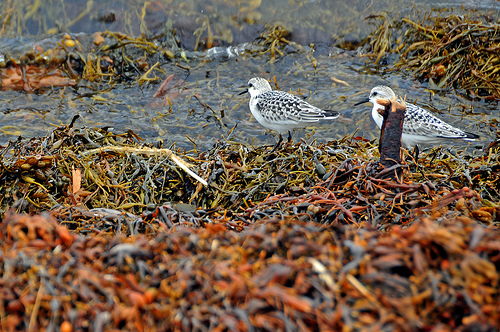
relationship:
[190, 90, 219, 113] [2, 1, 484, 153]
reed growing in water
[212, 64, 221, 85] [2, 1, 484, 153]
reed growing in water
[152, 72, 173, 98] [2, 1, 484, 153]
reed growing in water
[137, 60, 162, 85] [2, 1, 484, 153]
reed growing in water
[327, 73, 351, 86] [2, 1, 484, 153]
reed growing in water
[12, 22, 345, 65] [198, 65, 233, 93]
snake sliring in water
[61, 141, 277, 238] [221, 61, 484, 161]
seaweed near birds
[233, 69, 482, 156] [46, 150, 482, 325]
birds on ground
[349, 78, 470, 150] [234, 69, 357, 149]
bird next to bird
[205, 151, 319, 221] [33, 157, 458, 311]
stuff on ground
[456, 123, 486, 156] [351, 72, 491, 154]
feather on bird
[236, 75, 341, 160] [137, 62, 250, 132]
birds standing near water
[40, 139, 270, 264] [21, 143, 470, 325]
twigs on ground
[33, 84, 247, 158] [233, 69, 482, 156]
water near birds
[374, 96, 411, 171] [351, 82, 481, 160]
stick near bird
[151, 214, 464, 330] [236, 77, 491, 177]
plants in front of bird